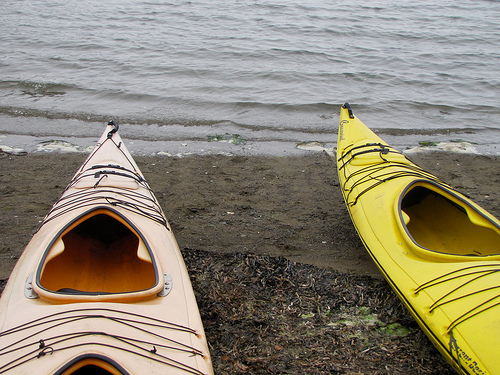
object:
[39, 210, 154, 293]
interior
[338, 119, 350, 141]
name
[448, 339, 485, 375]
brand name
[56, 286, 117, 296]
seat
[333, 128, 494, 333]
kayak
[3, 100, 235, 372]
kayak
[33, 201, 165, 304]
people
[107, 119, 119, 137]
handle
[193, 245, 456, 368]
seaweed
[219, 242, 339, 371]
debris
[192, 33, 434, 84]
waves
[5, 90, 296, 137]
waves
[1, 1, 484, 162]
ocean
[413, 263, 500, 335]
rope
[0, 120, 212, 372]
canoe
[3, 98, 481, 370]
sandy beach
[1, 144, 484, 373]
shore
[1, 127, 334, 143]
wave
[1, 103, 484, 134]
wave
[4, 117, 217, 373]
kayaks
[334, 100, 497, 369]
kayaks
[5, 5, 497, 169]
sea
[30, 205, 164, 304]
bracket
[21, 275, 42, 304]
bolts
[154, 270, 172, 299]
plate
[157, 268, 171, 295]
screws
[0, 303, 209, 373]
rope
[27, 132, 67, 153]
foam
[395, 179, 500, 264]
cockpit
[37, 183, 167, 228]
straps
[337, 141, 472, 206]
straps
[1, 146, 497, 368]
sand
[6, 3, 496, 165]
water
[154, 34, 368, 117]
water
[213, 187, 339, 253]
dirt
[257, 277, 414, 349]
leaves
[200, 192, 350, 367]
sand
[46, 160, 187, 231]
ties